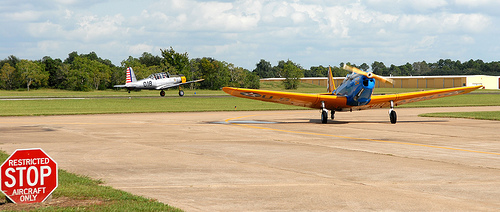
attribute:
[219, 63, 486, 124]
plane — private, yellow, blue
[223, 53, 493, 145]
plane — yellow, blue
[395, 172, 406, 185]
bench — brown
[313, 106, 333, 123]
wheel — black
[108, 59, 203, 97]
plane — parked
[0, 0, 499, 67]
clouds — white, thick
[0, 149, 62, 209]
sign — red, white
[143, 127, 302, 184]
sand — clean view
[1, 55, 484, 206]
airport — small, rural